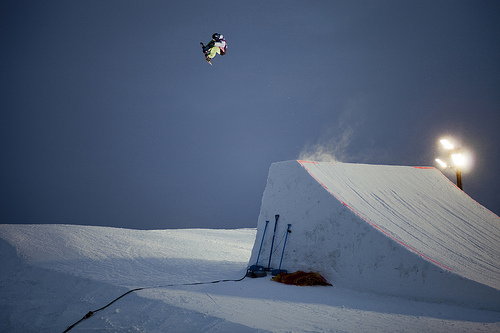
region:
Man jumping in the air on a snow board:
[178, 21, 238, 71]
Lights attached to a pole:
[425, 130, 471, 179]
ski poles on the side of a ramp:
[251, 207, 300, 271]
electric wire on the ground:
[81, 263, 269, 318]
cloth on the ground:
[272, 258, 341, 296]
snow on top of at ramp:
[330, 168, 450, 238]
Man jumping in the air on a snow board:
[197, 25, 227, 72]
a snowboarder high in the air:
[196, 28, 230, 63]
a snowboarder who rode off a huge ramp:
[197, 28, 229, 65]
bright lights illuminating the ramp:
[429, 124, 481, 196]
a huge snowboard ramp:
[242, 149, 499, 311]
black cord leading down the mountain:
[49, 273, 254, 332]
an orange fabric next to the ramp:
[269, 267, 330, 289]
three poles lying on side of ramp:
[252, 209, 296, 276]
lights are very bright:
[425, 124, 481, 190]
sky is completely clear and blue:
[1, 3, 498, 249]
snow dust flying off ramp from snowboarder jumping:
[290, 100, 364, 168]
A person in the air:
[186, 27, 248, 72]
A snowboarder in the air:
[193, 25, 231, 67]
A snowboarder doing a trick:
[196, 28, 229, 68]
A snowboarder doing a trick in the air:
[192, 31, 231, 73]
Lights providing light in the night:
[356, 130, 477, 173]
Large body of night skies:
[36, 47, 186, 214]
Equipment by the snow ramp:
[259, 214, 304, 279]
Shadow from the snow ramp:
[33, 245, 241, 315]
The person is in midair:
[191, 30, 234, 70]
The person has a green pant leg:
[207, 45, 221, 60]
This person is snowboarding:
[179, 18, 254, 78]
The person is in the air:
[181, 22, 257, 84]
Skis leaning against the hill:
[242, 201, 313, 274]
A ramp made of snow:
[237, 107, 495, 307]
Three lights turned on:
[406, 107, 483, 195]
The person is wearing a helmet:
[191, 20, 253, 74]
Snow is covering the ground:
[21, 171, 404, 331]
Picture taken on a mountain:
[28, 173, 453, 330]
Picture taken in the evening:
[17, 10, 487, 317]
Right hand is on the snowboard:
[196, 31, 239, 71]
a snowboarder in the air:
[180, 27, 267, 106]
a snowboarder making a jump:
[178, 11, 260, 92]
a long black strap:
[47, 257, 267, 332]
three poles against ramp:
[243, 194, 340, 302]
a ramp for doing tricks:
[247, 105, 497, 319]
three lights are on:
[418, 107, 475, 206]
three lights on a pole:
[419, 119, 481, 239]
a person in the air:
[189, 19, 266, 96]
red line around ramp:
[296, 146, 494, 263]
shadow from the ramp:
[37, 215, 470, 330]